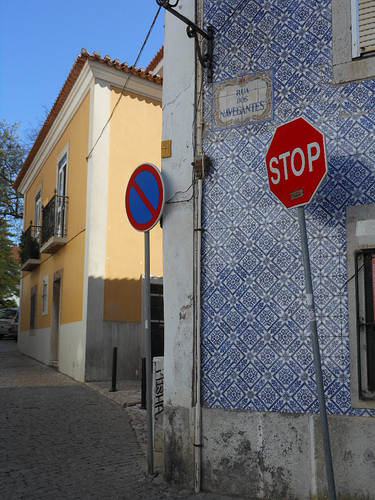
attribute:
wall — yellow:
[93, 86, 160, 283]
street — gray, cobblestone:
[3, 346, 158, 499]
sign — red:
[262, 119, 329, 206]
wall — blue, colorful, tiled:
[198, 6, 375, 410]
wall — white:
[166, 1, 196, 393]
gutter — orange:
[12, 53, 90, 194]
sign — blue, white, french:
[212, 84, 274, 123]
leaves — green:
[1, 132, 22, 223]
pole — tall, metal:
[291, 208, 336, 498]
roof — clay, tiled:
[144, 49, 167, 80]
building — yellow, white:
[22, 86, 164, 350]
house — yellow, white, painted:
[16, 47, 162, 383]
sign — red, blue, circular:
[124, 172, 163, 224]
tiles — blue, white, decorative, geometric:
[196, 6, 369, 416]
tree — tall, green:
[2, 103, 43, 252]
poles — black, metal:
[111, 350, 145, 404]